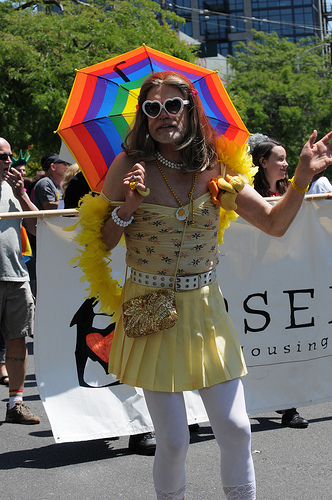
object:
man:
[89, 68, 331, 500]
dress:
[91, 161, 248, 393]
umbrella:
[53, 43, 251, 196]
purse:
[122, 289, 179, 337]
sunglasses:
[140, 96, 185, 120]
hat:
[10, 147, 31, 165]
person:
[0, 136, 41, 426]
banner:
[36, 196, 331, 444]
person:
[31, 153, 73, 303]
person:
[248, 138, 289, 198]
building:
[34, 0, 331, 105]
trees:
[2, 3, 212, 180]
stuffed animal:
[209, 171, 244, 212]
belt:
[129, 268, 216, 291]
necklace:
[154, 152, 198, 223]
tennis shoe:
[4, 400, 41, 426]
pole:
[0, 191, 331, 220]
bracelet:
[152, 151, 192, 172]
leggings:
[139, 375, 258, 499]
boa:
[71, 190, 127, 324]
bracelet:
[111, 206, 134, 228]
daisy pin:
[175, 205, 189, 222]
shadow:
[0, 430, 131, 468]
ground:
[1, 353, 330, 498]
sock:
[7, 386, 26, 409]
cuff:
[221, 484, 257, 499]